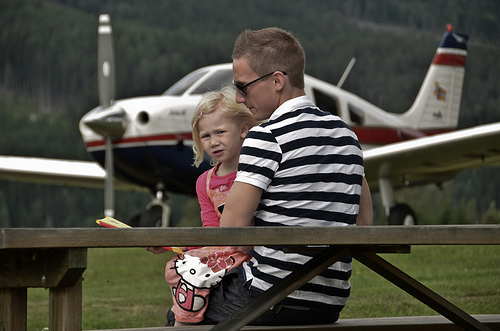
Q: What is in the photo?
A: A propellor.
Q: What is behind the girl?
A: A plane.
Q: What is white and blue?
A: A plane.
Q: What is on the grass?
A: A plane.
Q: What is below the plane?
A: Grass.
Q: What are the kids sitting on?
A: A bench.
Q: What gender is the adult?
A: Male.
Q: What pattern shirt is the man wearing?
A: Striped.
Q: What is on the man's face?
A: Sunglasses.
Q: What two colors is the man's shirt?
A: Black and white.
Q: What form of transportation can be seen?
A: Airplane.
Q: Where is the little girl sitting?
A: On man's lap.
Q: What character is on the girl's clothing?
A: Hello Kitty.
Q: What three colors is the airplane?
A: Red, white and blue.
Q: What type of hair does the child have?
A: Blonde.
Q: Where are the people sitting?
A: On a bench.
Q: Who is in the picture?
A: A man and a girl.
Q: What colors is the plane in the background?
A: Red, white and blue.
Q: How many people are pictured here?
A: Two.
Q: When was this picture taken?
A: Daytime.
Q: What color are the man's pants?
A: Black.